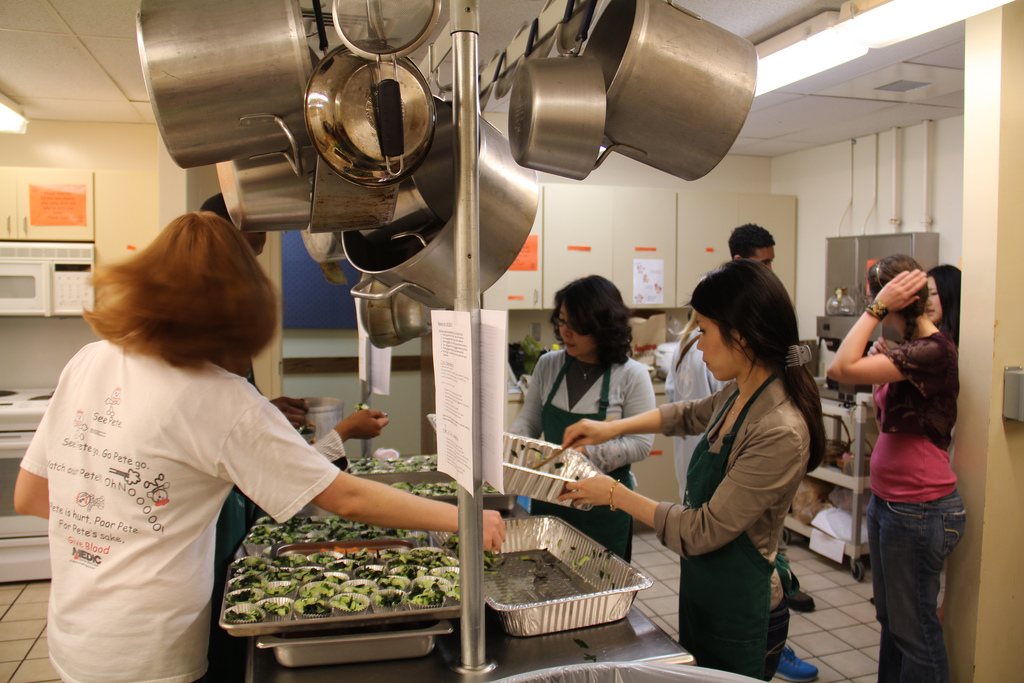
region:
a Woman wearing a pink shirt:
[824, 255, 979, 524]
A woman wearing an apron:
[656, 249, 799, 661]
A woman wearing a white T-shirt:
[25, 211, 338, 649]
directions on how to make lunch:
[422, 298, 495, 494]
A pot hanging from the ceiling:
[509, 10, 611, 185]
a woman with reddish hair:
[95, 206, 289, 368]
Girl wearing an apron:
[674, 355, 793, 678]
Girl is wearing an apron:
[683, 343, 807, 679]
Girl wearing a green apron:
[668, 352, 801, 679]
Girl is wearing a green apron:
[665, 355, 795, 679]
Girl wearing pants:
[852, 460, 973, 679]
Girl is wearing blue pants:
[855, 475, 977, 679]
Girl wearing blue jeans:
[845, 473, 975, 679]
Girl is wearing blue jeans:
[858, 465, 977, 680]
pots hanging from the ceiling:
[132, 2, 762, 301]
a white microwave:
[10, 249, 90, 306]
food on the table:
[234, 452, 620, 645]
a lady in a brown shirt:
[634, 262, 832, 654]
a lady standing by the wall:
[843, 259, 983, 652]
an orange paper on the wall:
[32, 183, 86, 231]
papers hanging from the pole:
[419, 310, 512, 498]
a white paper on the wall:
[631, 259, 664, 307]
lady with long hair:
[672, 249, 843, 505]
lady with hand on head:
[819, 236, 975, 429]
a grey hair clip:
[781, 326, 820, 377]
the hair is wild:
[59, 196, 285, 406]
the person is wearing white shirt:
[3, 199, 519, 671]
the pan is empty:
[461, 474, 658, 649]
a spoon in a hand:
[520, 410, 587, 490]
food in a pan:
[171, 524, 462, 639]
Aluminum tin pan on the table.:
[480, 497, 648, 635]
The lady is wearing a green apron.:
[669, 395, 786, 645]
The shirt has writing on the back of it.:
[32, 392, 219, 579]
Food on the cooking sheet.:
[246, 512, 482, 608]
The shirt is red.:
[872, 392, 946, 491]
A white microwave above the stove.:
[3, 246, 115, 311]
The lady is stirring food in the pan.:
[487, 388, 804, 548]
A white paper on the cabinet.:
[623, 255, 671, 325]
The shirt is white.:
[54, 398, 217, 640]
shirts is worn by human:
[640, 381, 808, 606]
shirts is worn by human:
[508, 349, 664, 479]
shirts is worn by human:
[24, 323, 342, 678]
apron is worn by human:
[672, 370, 799, 677]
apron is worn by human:
[529, 336, 638, 577]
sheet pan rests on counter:
[465, 503, 652, 636]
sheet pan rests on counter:
[223, 520, 467, 664]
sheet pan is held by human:
[479, 431, 603, 511]